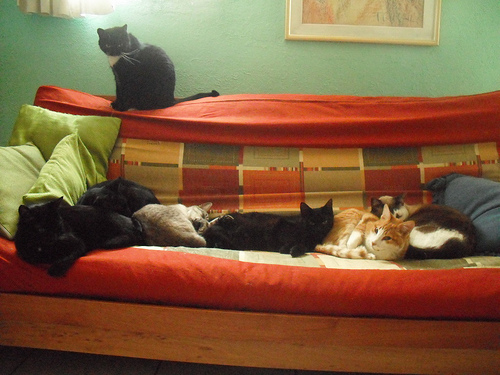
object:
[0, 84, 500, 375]
sofa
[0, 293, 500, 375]
wood frame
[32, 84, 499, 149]
cover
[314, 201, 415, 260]
cat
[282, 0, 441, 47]
picture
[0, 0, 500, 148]
wall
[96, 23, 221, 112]
cat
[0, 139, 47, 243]
pillow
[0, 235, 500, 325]
futon cushion